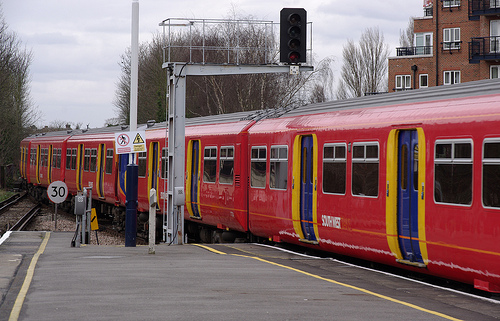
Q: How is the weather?
A: It is cloudy.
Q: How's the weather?
A: It is cloudy.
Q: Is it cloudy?
A: Yes, it is cloudy.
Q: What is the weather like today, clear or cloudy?
A: It is cloudy.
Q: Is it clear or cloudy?
A: It is cloudy.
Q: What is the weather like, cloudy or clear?
A: It is cloudy.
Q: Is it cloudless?
A: No, it is cloudy.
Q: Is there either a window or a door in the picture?
A: Yes, there is a door.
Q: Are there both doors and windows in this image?
A: Yes, there are both a door and windows.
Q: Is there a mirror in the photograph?
A: No, there are no mirrors.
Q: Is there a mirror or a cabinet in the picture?
A: No, there are no mirrors or cabinets.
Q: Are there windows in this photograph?
A: Yes, there are windows.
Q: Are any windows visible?
A: Yes, there are windows.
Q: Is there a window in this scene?
A: Yes, there are windows.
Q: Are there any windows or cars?
A: Yes, there are windows.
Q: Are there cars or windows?
A: Yes, there are windows.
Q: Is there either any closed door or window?
A: Yes, there are closed windows.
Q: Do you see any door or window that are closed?
A: Yes, the windows are closed.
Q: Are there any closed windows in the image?
A: Yes, there are closed windows.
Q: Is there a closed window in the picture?
A: Yes, there are closed windows.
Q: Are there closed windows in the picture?
A: Yes, there are closed windows.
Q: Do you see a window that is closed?
A: Yes, there are windows that are closed.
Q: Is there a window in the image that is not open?
A: Yes, there are closed windows.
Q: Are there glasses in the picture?
A: No, there are no glasses.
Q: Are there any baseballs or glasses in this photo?
A: No, there are no glasses or baseballs.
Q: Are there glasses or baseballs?
A: No, there are no glasses or baseballs.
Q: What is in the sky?
A: The clouds are in the sky.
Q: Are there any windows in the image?
A: Yes, there are windows.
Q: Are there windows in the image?
A: Yes, there are windows.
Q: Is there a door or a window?
A: Yes, there are windows.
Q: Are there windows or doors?
A: Yes, there are windows.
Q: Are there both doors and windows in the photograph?
A: Yes, there are both windows and a door.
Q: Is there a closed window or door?
A: Yes, there are closed windows.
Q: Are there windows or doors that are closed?
A: Yes, the windows are closed.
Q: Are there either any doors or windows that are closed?
A: Yes, the windows are closed.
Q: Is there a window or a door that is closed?
A: Yes, the windows are closed.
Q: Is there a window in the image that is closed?
A: Yes, there are closed windows.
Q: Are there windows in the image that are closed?
A: Yes, there are windows that are closed.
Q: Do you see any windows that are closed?
A: Yes, there are windows that are closed.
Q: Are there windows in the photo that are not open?
A: Yes, there are closed windows.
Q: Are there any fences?
A: No, there are no fences.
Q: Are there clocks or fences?
A: No, there are no fences or clocks.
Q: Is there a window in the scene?
A: Yes, there are windows.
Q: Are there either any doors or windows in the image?
A: Yes, there are windows.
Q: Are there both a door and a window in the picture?
A: Yes, there are both a window and a door.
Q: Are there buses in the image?
A: No, there are no buses.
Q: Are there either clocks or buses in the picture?
A: No, there are no buses or clocks.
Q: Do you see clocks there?
A: No, there are no clocks.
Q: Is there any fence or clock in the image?
A: No, there are no clocks or fences.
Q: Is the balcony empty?
A: Yes, the balcony is empty.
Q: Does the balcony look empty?
A: Yes, the balcony is empty.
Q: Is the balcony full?
A: No, the balcony is empty.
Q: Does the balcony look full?
A: No, the balcony is empty.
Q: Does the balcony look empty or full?
A: The balcony is empty.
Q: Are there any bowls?
A: No, there are no bowls.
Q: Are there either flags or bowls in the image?
A: No, there are no bowls or flags.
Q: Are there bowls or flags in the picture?
A: No, there are no bowls or flags.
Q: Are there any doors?
A: Yes, there is a door.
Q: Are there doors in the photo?
A: Yes, there is a door.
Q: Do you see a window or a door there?
A: Yes, there is a door.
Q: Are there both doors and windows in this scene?
A: Yes, there are both a door and windows.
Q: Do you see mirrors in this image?
A: No, there are no mirrors.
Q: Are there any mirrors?
A: No, there are no mirrors.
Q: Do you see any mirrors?
A: No, there are no mirrors.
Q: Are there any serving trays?
A: No, there are no serving trays.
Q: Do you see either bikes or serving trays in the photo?
A: No, there are no serving trays or bikes.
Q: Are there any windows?
A: Yes, there are windows.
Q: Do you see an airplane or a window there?
A: Yes, there are windows.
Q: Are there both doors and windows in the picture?
A: Yes, there are both windows and a door.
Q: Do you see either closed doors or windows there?
A: Yes, there are closed windows.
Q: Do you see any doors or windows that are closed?
A: Yes, the windows are closed.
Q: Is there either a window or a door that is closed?
A: Yes, the windows are closed.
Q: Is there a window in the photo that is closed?
A: Yes, there are closed windows.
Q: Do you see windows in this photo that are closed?
A: Yes, there are windows that are closed.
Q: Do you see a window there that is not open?
A: Yes, there are closed windows.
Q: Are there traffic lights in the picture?
A: Yes, there is a traffic light.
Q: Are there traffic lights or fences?
A: Yes, there is a traffic light.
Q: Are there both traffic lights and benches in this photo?
A: No, there is a traffic light but no benches.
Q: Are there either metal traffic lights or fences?
A: Yes, there is a metal traffic light.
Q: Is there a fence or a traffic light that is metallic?
A: Yes, the traffic light is metallic.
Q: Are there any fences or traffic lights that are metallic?
A: Yes, the traffic light is metallic.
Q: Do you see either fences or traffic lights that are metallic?
A: Yes, the traffic light is metallic.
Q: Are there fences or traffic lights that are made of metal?
A: Yes, the traffic light is made of metal.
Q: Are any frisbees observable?
A: No, there are no frisbees.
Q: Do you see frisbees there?
A: No, there are no frisbees.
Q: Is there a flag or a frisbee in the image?
A: No, there are no frisbees or flags.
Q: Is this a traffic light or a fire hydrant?
A: This is a traffic light.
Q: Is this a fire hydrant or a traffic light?
A: This is a traffic light.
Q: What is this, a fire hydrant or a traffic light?
A: This is a traffic light.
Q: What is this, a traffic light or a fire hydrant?
A: This is a traffic light.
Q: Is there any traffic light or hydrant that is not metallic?
A: No, there is a traffic light but it is metallic.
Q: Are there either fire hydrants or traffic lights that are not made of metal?
A: No, there is a traffic light but it is made of metal.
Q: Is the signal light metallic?
A: Yes, the signal light is metallic.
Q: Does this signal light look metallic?
A: Yes, the signal light is metallic.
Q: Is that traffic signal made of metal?
A: Yes, the traffic signal is made of metal.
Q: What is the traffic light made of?
A: The traffic light is made of metal.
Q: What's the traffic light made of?
A: The traffic light is made of metal.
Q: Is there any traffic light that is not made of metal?
A: No, there is a traffic light but it is made of metal.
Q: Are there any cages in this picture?
A: No, there are no cages.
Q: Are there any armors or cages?
A: No, there are no cages or armors.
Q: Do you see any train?
A: Yes, there is a train.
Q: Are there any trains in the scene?
A: Yes, there is a train.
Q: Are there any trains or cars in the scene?
A: Yes, there is a train.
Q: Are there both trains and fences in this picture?
A: No, there is a train but no fences.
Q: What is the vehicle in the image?
A: The vehicle is a train.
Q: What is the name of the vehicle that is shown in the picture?
A: The vehicle is a train.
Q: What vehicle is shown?
A: The vehicle is a train.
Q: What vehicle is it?
A: The vehicle is a train.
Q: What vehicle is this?
A: This is a train.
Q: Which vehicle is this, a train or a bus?
A: This is a train.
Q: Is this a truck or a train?
A: This is a train.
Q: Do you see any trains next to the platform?
A: Yes, there is a train next to the platform.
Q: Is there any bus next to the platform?
A: No, there is a train next to the platform.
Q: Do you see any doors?
A: Yes, there is a door.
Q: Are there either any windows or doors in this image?
A: Yes, there is a door.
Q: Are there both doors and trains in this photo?
A: Yes, there are both a door and a train.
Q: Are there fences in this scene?
A: No, there are no fences.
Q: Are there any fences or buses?
A: No, there are no fences or buses.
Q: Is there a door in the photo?
A: Yes, there is a door.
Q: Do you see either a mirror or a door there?
A: Yes, there is a door.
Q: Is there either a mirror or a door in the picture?
A: Yes, there is a door.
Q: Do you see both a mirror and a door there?
A: No, there is a door but no mirrors.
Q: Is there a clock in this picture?
A: No, there are no clocks.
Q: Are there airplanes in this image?
A: No, there are no airplanes.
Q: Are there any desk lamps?
A: No, there are no desk lamps.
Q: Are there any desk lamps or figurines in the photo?
A: No, there are no desk lamps or figurines.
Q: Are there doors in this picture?
A: Yes, there is a door.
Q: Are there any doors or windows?
A: Yes, there is a door.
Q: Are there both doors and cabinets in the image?
A: No, there is a door but no cabinets.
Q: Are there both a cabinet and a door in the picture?
A: No, there is a door but no cabinets.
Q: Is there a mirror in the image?
A: No, there are no mirrors.